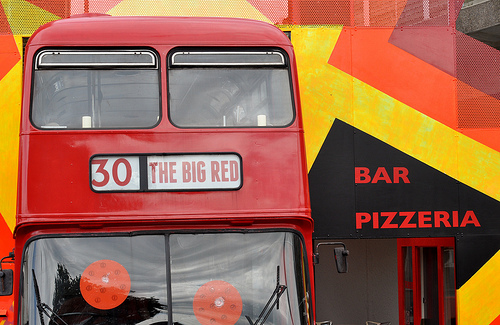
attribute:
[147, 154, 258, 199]
words — the, big, red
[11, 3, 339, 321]
bus — double decker, red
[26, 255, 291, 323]
wipers — windshield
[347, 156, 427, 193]
word — bar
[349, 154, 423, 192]
letters — red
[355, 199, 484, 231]
letters — red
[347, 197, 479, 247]
word — PIZZERIA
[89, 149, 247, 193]
sign — white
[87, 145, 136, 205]
numbers — red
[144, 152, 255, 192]
letters — red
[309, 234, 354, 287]
mirror — side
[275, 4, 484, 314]
building — colorful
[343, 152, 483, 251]
words — red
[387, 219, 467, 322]
door — red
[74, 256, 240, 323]
circles — red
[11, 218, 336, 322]
window — bus